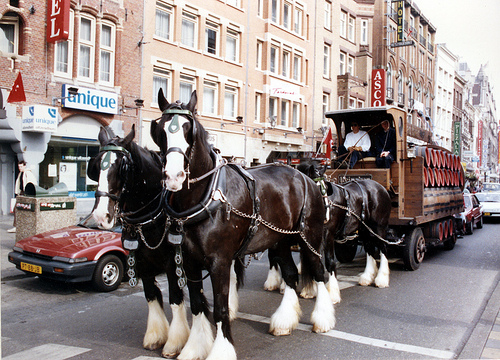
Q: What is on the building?
A: The sign is on the building.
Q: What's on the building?
A: The sign is on the building.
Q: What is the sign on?
A: The sign is on the building.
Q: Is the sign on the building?
A: Yes, the sign is on the building.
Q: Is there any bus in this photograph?
A: No, there are no buses.